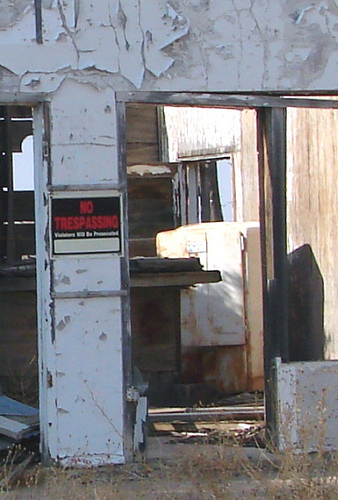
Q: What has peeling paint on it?
A: The wall.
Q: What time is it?
A: Afternoon.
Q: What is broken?
A: The wall.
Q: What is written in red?
A: The sign.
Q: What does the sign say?
A: No Trespassing.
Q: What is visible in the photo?
A: A sign.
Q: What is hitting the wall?
A: Light.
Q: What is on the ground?
A: Dirt.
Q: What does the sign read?
A: No trespassing.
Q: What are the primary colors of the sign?
A: Black and red are the primary colors.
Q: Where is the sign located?
A: The sign is located on the wall.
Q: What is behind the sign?
A: A post of a wall.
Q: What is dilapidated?
A: The building is dilapidated.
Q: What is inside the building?
A: An old refrigerator.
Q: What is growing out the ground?
A: Weeds are growing here.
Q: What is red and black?
A: The sign.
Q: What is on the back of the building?
A: Window.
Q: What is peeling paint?
A: Part of a house.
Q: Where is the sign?
A: On the column.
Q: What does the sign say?
A: No trespassing.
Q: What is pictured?
A: An abandoned building.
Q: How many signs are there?
A: One.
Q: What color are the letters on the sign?
A: Red.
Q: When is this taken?
A: Daytime.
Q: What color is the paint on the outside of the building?
A: White.